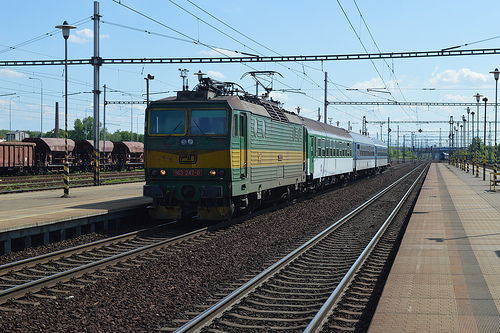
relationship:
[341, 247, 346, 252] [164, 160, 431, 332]
pebble on track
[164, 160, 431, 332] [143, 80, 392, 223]
track beside train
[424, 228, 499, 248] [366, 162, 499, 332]
shadow on ground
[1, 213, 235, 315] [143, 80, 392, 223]
track in front of train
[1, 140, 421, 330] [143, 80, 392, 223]
gravel next to train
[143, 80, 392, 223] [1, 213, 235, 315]
train on track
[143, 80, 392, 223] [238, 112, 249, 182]
train has a door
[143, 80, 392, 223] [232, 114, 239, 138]
train has a window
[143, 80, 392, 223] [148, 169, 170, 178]
train has a headlight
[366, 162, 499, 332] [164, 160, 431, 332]
platform near track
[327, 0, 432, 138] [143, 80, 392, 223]
wire above train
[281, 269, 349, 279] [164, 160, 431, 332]
crosstie on track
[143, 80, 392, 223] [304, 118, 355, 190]
train pulling a car